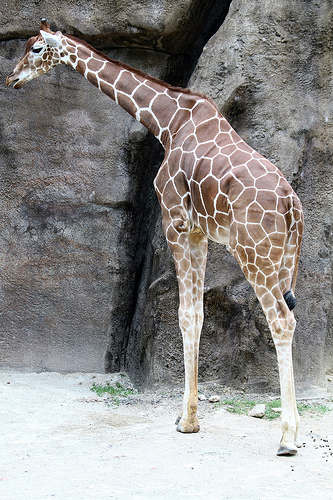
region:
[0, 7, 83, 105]
the giraffe looks sleepy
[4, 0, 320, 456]
the giraffe is very tall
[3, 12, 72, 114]
the giraffe has his mouth slightly open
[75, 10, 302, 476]
the giraffe is brown and white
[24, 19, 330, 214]
the giraffe has an interesting pattern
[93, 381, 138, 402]
the grass at his feet is sparse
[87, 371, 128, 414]
the grass at his feet is green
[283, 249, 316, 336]
the end of his tail is black.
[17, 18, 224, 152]
the giraffe has a very long neck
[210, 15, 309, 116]
the rocks behind the giraffe are huge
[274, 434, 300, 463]
hoof on the back foot of a giraffe.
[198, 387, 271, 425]
three rocks on the ground.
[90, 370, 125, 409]
scrubby grass on the ground.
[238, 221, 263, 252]
brown spots on a giraffe.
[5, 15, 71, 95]
head of a giraffe.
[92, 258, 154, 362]
crack in a rock.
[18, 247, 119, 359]
grey side of a rock.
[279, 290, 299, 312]
black tip of a giraffe tail.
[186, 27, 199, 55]
blackness in a rock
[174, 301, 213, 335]
knees of the front legs of a giraffe.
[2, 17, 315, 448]
tall giraffe in zoo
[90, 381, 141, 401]
small patch of green grass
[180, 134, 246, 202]
brown spots on giraffe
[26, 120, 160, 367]
rocks keeping giraffe enclosed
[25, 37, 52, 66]
giraffe with black eyes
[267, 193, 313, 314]
thin giraffe tail with black bottom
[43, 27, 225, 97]
thin line of brown fur along giraffes back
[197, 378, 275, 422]
small rocks on ground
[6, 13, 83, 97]
giraffe with mouth slightly open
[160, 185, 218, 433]
tall skinny giraffe legs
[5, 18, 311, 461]
giraffe standing on flat ground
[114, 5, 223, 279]
giraffe in front of dark crevice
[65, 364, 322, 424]
grass growing at bottom of wall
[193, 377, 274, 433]
rocks behind giraffe's feet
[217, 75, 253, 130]
oval opening behind giraffe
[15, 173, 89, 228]
wide bump on wall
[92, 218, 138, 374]
angular edge to stone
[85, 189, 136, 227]
notch on the side of wall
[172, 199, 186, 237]
dimpled opening on giraffe's thigh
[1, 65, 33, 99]
lips apart on giraffe's mouth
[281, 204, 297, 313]
Tail of a giraffe standing by a rock wall.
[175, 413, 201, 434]
Two front hooves of a giraffe.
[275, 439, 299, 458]
Back left hoof of a giraffe.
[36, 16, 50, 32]
Boney horns on top of a giraffes head.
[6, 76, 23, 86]
Giraffe's mouth that is open.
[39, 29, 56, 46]
Left ear of a giraffe.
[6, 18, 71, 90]
Head of a giraffe with its mouth open.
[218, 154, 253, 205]
Group of brown spots on a giraffe.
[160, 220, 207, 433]
Two front legs of a giraffe standing by a rock wall.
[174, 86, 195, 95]
Small patch of brown hair on a giraffes long neck.